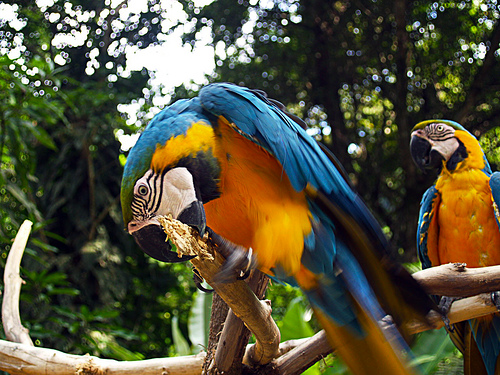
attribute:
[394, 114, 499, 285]
bird — colorful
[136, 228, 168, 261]
beak — black, upper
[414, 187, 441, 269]
wing — blue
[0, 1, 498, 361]
leaves — green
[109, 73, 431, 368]
claw — black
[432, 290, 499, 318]
claws — black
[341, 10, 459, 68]
leaves — green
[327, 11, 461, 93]
leaves — green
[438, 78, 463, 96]
leaves — green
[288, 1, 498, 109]
trees — green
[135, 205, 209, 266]
beak — black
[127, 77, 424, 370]
bird — large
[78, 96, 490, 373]
parrot — colorful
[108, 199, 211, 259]
beak — sharp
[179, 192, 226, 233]
beak — black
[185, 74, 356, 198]
wing — blue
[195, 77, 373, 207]
wing — blue